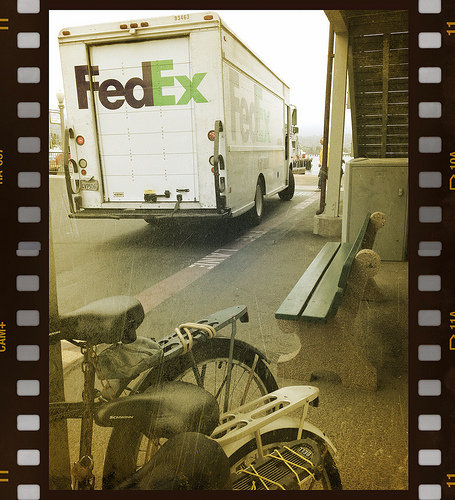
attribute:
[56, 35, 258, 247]
truck — large, white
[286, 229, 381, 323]
bench — green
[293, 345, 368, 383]
support — cement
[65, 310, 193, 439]
seats — black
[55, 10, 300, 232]
truck — delivery